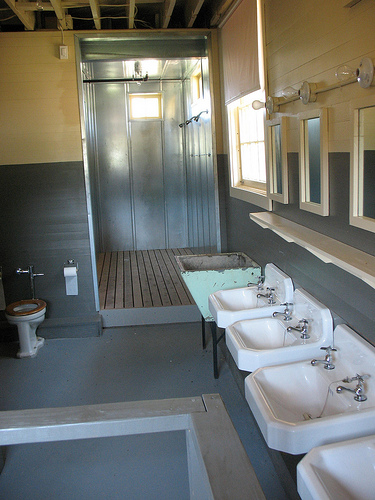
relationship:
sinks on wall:
[208, 263, 374, 499] [209, 2, 363, 471]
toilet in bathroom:
[1, 269, 50, 359] [3, 0, 363, 498]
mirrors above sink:
[264, 94, 374, 234] [219, 287, 334, 372]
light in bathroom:
[249, 94, 281, 117] [3, 0, 363, 498]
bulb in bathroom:
[333, 56, 362, 83] [3, 0, 363, 498]